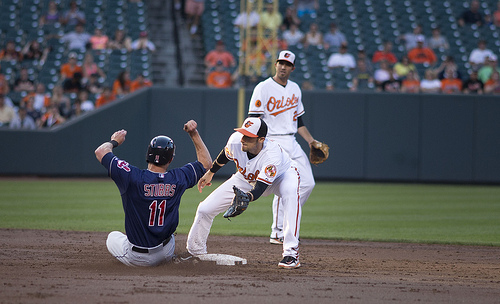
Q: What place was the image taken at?
A: It was taken at the field.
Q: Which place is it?
A: It is a field.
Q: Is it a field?
A: Yes, it is a field.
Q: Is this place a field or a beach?
A: It is a field.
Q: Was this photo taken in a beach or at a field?
A: It was taken at a field.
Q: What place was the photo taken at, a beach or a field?
A: It was taken at a field.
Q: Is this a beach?
A: No, it is a field.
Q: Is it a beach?
A: No, it is a field.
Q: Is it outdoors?
A: Yes, it is outdoors.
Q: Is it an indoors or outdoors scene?
A: It is outdoors.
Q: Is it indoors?
A: No, it is outdoors.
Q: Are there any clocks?
A: No, there are no clocks.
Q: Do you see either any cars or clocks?
A: No, there are no clocks or cars.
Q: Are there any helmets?
A: Yes, there is a helmet.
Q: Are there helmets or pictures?
A: Yes, there is a helmet.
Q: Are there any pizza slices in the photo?
A: No, there are no pizza slices.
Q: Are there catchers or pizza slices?
A: No, there are no pizza slices or catchers.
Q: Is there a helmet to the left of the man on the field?
A: Yes, there is a helmet to the left of the man.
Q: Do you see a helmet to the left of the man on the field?
A: Yes, there is a helmet to the left of the man.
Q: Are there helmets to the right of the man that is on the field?
A: No, the helmet is to the left of the man.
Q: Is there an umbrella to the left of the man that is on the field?
A: No, there is a helmet to the left of the man.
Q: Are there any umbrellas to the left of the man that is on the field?
A: No, there is a helmet to the left of the man.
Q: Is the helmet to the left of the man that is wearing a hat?
A: Yes, the helmet is to the left of the man.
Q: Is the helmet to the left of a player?
A: No, the helmet is to the left of the man.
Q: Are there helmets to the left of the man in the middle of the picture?
A: Yes, there is a helmet to the left of the man.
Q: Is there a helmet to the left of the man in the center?
A: Yes, there is a helmet to the left of the man.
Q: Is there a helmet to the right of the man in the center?
A: No, the helmet is to the left of the man.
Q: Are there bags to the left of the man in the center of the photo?
A: No, there is a helmet to the left of the man.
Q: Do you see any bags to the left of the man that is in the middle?
A: No, there is a helmet to the left of the man.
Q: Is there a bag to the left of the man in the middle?
A: No, there is a helmet to the left of the man.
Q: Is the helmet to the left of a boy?
A: No, the helmet is to the left of the man.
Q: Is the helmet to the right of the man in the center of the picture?
A: No, the helmet is to the left of the man.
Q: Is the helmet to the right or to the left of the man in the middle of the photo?
A: The helmet is to the left of the man.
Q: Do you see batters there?
A: No, there are no batters.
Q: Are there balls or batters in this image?
A: No, there are no batters or balls.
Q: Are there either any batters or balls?
A: No, there are no batters or balls.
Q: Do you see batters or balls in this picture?
A: No, there are no batters or balls.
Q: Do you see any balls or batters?
A: No, there are no batters or balls.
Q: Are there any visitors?
A: No, there are no visitors.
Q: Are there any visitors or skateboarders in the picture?
A: No, there are no visitors or skateboarders.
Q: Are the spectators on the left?
A: Yes, the spectators are on the left of the image.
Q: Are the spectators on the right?
A: No, the spectators are on the left of the image.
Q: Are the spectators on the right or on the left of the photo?
A: The spectators are on the left of the image.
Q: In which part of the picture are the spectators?
A: The spectators are on the left of the image.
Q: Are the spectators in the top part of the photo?
A: Yes, the spectators are in the top of the image.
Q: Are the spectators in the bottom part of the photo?
A: No, the spectators are in the top of the image.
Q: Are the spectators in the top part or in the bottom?
A: The spectators are in the top of the image.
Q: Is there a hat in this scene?
A: Yes, there is a hat.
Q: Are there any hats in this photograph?
A: Yes, there is a hat.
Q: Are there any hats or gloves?
A: Yes, there is a hat.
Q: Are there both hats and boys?
A: No, there is a hat but no boys.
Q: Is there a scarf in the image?
A: No, there are no scarves.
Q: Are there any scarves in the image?
A: No, there are no scarves.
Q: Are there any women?
A: No, there are no women.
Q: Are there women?
A: No, there are no women.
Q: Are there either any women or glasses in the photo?
A: No, there are no women or glasses.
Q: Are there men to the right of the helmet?
A: Yes, there is a man to the right of the helmet.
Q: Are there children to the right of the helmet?
A: No, there is a man to the right of the helmet.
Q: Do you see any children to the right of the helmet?
A: No, there is a man to the right of the helmet.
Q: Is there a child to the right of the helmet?
A: No, there is a man to the right of the helmet.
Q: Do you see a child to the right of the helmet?
A: No, there is a man to the right of the helmet.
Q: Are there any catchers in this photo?
A: No, there are no catchers.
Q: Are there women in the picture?
A: No, there are no women.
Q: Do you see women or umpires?
A: No, there are no women or umpires.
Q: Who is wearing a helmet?
A: The man is wearing a helmet.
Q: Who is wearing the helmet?
A: The man is wearing a helmet.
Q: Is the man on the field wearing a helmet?
A: Yes, the man is wearing a helmet.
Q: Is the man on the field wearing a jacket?
A: No, the man is wearing a helmet.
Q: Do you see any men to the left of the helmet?
A: No, the man is to the right of the helmet.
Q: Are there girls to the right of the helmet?
A: No, there is a man to the right of the helmet.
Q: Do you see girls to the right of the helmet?
A: No, there is a man to the right of the helmet.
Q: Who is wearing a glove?
A: The man is wearing a glove.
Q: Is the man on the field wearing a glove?
A: Yes, the man is wearing a glove.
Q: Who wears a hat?
A: The man wears a hat.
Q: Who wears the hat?
A: The man wears a hat.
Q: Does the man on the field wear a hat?
A: Yes, the man wears a hat.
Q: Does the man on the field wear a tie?
A: No, the man wears a hat.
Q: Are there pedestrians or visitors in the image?
A: No, there are no visitors or pedestrians.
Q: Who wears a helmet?
A: The man wears a helmet.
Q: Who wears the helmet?
A: The man wears a helmet.